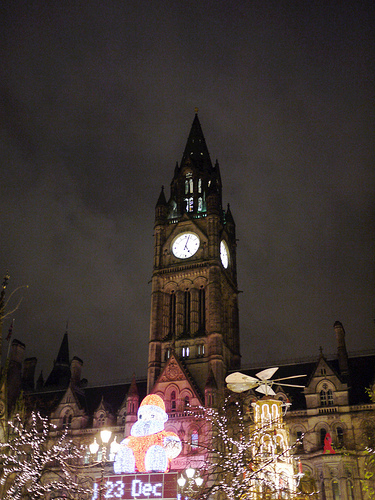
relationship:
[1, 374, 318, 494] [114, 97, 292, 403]
lights on building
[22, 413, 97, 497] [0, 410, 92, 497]
lights on tree